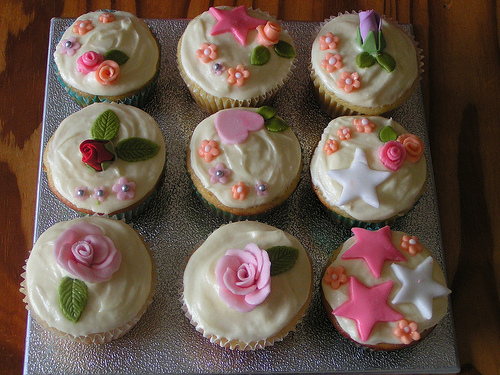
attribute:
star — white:
[389, 253, 450, 324]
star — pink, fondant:
[334, 271, 402, 340]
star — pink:
[341, 226, 409, 277]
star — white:
[327, 147, 394, 207]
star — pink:
[210, 5, 270, 44]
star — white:
[391, 255, 452, 319]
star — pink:
[333, 275, 403, 342]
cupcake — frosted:
[311, 117, 427, 228]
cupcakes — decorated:
[20, 213, 314, 352]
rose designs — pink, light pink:
[52, 220, 300, 324]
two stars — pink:
[333, 225, 407, 340]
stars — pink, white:
[342, 226, 453, 318]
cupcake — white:
[189, 107, 306, 218]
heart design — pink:
[216, 109, 267, 144]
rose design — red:
[79, 138, 117, 172]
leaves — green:
[92, 109, 161, 162]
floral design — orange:
[319, 32, 360, 92]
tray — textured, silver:
[24, 17, 462, 374]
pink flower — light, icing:
[60, 36, 80, 55]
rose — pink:
[56, 223, 123, 284]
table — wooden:
[0, 0, 499, 374]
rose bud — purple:
[358, 8, 385, 55]